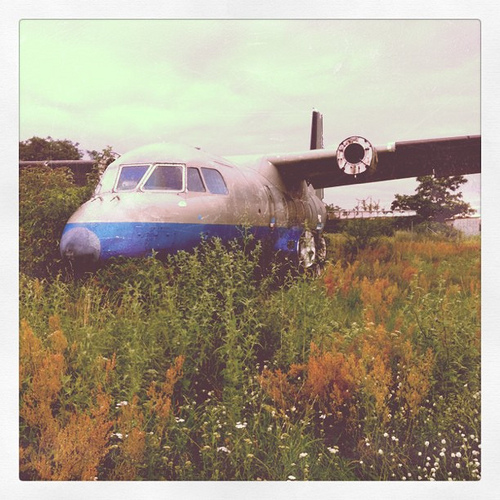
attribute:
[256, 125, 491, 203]
wing — white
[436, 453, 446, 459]
flowers — white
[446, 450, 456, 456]
flowers — white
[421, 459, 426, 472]
flowers — white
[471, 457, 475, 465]
flowers — white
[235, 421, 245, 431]
flowers — white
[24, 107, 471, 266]
plane — blue, white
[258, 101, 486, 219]
wing — white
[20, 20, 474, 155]
sky — grey, white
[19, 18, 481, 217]
sky — grey, cloudy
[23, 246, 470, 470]
vegetation — green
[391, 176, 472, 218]
leaves — green 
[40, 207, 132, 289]
nose — grey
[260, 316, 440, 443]
plant — orange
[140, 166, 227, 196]
window — glass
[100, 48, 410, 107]
clouds — light dark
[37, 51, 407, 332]
plane — downed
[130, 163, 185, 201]
window — glass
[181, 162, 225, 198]
window — glass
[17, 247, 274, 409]
grass — green, weedy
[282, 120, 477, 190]
wing — white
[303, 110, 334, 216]
tail — black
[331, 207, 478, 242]
building — grey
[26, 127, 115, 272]
greentrees — tall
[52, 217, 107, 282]
nose — grey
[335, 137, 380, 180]
engine — gray